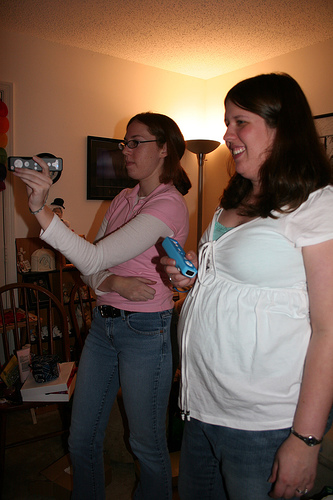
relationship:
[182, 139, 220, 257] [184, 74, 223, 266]
floor lamp in corner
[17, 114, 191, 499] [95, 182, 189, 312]
girl wearing a shirt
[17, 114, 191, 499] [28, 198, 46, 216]
girl wearing a bracelet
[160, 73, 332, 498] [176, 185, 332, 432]
woman wearing a shirt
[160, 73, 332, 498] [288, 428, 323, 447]
woman wearing a watch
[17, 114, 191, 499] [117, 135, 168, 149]
girl wearing glasses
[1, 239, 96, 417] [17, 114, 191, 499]
shelves behind girl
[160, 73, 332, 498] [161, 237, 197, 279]
woman holding wiimote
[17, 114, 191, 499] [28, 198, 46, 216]
girl wearing bracelet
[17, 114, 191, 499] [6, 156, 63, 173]
girl holding wiimote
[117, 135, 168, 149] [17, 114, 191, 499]
glasses on girl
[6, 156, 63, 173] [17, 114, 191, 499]
wiimote in hand of girl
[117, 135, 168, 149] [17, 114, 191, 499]
glasses on face of girl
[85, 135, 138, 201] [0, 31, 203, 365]
picture on wall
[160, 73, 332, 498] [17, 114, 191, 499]
woman playing with girl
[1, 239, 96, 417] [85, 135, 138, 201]
shelves near picture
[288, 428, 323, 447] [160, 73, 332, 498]
watch on woman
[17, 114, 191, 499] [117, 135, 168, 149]
girl wearing a pair of glasses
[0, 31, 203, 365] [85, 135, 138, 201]
wall has a hanging picture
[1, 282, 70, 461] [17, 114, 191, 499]
chair next to girl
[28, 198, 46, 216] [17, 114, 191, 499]
bracelet on girl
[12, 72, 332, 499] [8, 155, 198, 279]
women are holding wiimotes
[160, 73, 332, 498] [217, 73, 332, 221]
woman has hair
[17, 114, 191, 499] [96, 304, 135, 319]
girl wearing a belt